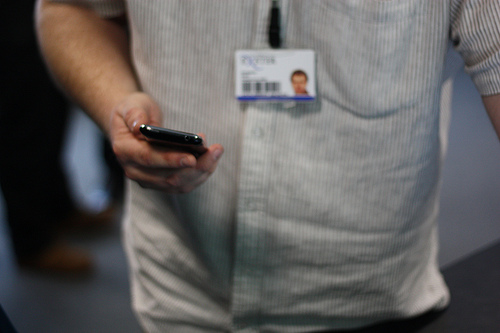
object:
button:
[247, 199, 260, 211]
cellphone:
[138, 124, 206, 158]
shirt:
[123, 1, 498, 332]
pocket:
[319, 11, 439, 129]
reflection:
[128, 118, 139, 135]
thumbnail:
[126, 118, 142, 133]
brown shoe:
[7, 240, 99, 282]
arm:
[35, 0, 145, 111]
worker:
[30, 0, 500, 333]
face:
[290, 69, 309, 95]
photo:
[2, 0, 492, 332]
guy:
[32, 0, 500, 333]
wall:
[413, 97, 495, 251]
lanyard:
[266, 1, 283, 50]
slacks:
[1, 1, 89, 258]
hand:
[104, 90, 223, 195]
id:
[232, 49, 319, 102]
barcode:
[242, 79, 281, 94]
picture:
[283, 64, 314, 99]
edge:
[126, 6, 450, 332]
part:
[135, 2, 221, 56]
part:
[349, 64, 430, 259]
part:
[445, 254, 472, 301]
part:
[297, 199, 355, 235]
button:
[250, 126, 265, 139]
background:
[5, 6, 122, 330]